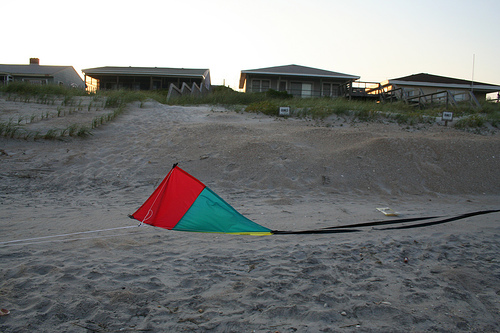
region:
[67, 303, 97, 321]
foot print in sand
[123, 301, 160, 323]
foot print in sand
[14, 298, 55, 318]
foot print in sand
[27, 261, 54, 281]
foot print in sand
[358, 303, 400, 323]
foot print in sand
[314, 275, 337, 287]
foot print in sand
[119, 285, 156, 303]
the dark brown sand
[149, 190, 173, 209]
the red of the kite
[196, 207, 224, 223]
the green of the kite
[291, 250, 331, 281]
foot prints in the sand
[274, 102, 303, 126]
a white sign on the hill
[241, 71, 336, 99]
a house above the beach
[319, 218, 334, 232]
the black strings of the kite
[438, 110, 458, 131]
another white sign on the beach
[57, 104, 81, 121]
little green brushes on the beach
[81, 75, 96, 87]
the sunset at the beach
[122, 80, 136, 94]
a window on a building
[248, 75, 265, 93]
a window on a building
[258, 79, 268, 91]
a window on a building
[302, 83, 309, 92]
a window on a building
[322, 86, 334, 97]
a window on a building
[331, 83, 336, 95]
a window on a building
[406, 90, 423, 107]
a window on a building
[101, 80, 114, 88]
a window on a building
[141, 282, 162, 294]
a footstep in the ground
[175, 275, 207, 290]
a footstep in the ground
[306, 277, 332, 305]
a footstep in the ground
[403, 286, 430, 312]
a footstep in the ground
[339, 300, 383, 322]
a footstep in the ground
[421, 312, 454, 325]
a footstep in the ground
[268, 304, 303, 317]
a footstep in the ground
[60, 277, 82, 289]
a footstep in the ground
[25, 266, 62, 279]
a footstep in the ground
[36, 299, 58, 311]
a footstep in the ground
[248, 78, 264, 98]
a window on a house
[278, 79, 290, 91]
a window on a house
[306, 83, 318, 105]
a window on a house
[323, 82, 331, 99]
a window on a house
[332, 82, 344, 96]
a window on a house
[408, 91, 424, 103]
a window on a house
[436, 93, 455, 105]
a window on a house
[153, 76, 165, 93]
a window on a house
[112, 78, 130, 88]
a window on a house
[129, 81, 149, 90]
a window on a house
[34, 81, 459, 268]
this is along a coast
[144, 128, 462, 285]
this is on a beach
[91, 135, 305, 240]
this is a kite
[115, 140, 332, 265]
the kite is colorful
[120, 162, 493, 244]
A kite on the sand.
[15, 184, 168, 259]
A string tied to the kite.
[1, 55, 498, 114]
A row of houses on the hill.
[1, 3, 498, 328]
a scene during the day time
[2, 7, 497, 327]
a scene outside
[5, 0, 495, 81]
a white sky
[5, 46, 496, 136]
a row of buildings in the background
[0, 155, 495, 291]
a colorful kite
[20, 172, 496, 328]
a shoreline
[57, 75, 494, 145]
green grass in the background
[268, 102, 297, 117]
a white little sign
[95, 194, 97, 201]
a piece of the image